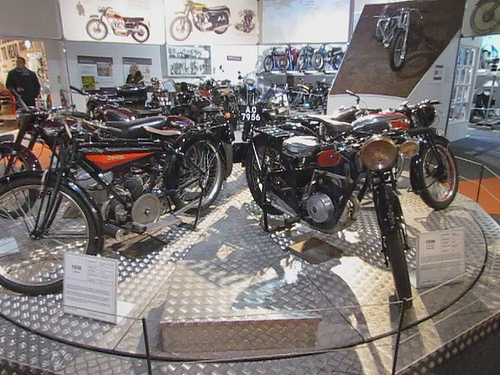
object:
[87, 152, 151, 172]
red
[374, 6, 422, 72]
bicycle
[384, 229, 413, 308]
front wheel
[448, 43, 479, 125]
fence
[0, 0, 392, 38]
wall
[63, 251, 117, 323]
sign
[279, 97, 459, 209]
motorbike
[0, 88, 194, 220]
motorbike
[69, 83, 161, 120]
motorbike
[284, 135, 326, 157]
seat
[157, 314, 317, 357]
pedestal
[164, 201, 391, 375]
shadow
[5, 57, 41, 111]
man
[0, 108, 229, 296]
motorbike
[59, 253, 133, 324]
yellow sticker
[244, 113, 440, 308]
bikes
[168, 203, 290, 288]
shadow casted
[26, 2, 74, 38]
ceiling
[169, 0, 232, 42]
yellow/black bike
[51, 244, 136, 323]
sign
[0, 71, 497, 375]
display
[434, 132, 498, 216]
floor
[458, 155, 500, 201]
stripe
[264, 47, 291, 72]
bike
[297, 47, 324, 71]
bike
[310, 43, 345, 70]
bike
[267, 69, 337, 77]
wall shelf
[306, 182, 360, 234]
engine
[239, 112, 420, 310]
motorcycle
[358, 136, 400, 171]
head light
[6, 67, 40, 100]
coat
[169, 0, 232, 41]
motorcycle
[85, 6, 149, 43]
motorcycle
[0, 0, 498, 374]
store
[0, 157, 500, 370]
wall shelf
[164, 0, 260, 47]
wall display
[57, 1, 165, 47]
wall display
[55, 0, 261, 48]
posters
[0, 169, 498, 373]
turntable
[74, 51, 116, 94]
sign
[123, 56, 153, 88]
sign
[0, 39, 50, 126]
doorway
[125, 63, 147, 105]
woman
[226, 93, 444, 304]
bike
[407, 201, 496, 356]
shadow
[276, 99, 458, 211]
bike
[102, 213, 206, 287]
shadow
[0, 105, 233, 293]
bike